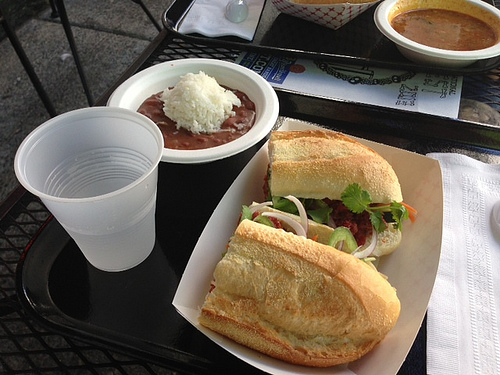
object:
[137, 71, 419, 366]
food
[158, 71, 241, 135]
rice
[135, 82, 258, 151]
beans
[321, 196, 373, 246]
piece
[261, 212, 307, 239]
onion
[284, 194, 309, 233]
onion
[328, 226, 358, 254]
pepper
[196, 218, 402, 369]
bread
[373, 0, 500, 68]
dish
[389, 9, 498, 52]
food